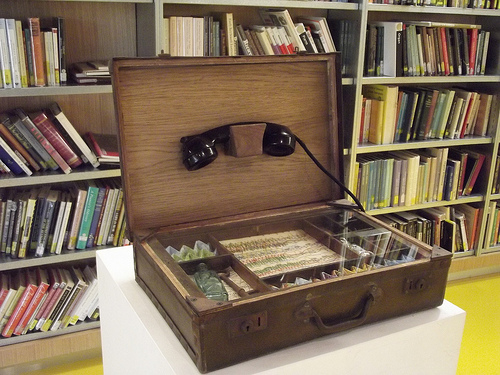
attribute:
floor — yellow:
[444, 273, 499, 374]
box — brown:
[102, 57, 454, 369]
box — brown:
[122, 39, 481, 340]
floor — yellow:
[398, 241, 499, 368]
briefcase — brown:
[97, 44, 466, 349]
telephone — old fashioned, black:
[165, 95, 342, 187]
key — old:
[224, 258, 263, 299]